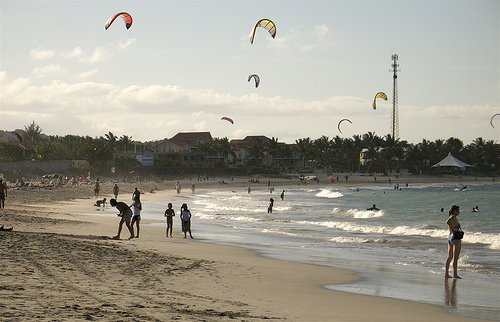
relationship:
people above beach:
[110, 189, 192, 235] [0, 177, 498, 318]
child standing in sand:
[179, 203, 195, 239] [0, 175, 497, 320]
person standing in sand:
[160, 201, 177, 237] [0, 175, 497, 320]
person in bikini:
[439, 198, 468, 282] [443, 216, 464, 244]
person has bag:
[439, 198, 468, 282] [454, 229, 464, 239]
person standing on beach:
[439, 198, 468, 282] [0, 177, 498, 318]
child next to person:
[179, 203, 191, 238] [160, 201, 177, 237]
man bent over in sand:
[108, 197, 133, 241] [43, 240, 233, 311]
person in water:
[356, 200, 385, 216] [311, 213, 441, 251]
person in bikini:
[439, 198, 468, 282] [445, 221, 465, 254]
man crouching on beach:
[103, 192, 135, 236] [109, 250, 234, 315]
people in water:
[469, 200, 484, 212] [132, 160, 499, 318]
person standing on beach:
[439, 198, 468, 282] [24, 236, 248, 288]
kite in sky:
[104, 11, 132, 29] [0, 0, 497, 144]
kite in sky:
[248, 19, 277, 44] [0, 0, 497, 144]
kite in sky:
[248, 73, 259, 87] [0, 0, 497, 144]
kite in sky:
[218, 116, 235, 124] [0, 0, 497, 144]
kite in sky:
[371, 90, 390, 108] [0, 0, 497, 144]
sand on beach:
[51, 253, 210, 301] [7, 167, 496, 322]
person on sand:
[439, 198, 477, 284] [3, 232, 375, 320]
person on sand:
[260, 194, 281, 219] [3, 232, 375, 320]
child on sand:
[179, 203, 195, 239] [3, 232, 375, 320]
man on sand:
[108, 197, 133, 241] [3, 232, 375, 320]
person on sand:
[160, 201, 180, 240] [3, 232, 375, 320]